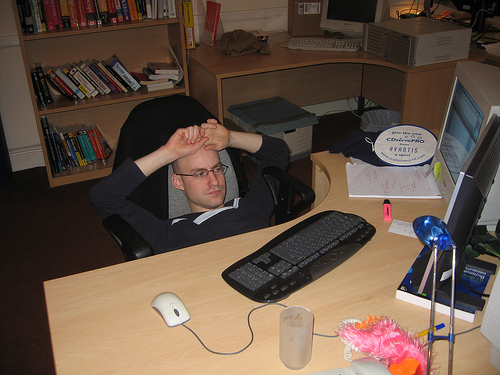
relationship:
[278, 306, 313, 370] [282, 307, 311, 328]
glass for drinking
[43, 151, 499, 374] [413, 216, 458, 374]
desk has a lamp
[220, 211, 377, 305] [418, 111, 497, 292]
keyboard to a computer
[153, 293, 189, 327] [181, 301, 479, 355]
mouse has a wire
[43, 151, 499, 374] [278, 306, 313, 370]
desk has a glass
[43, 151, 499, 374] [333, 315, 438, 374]
desk has a object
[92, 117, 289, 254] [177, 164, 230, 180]
man has on glasses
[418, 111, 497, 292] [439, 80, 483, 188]
computer has a screen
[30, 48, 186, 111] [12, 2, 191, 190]
books are on a book shelf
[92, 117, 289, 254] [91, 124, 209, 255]
man has a left arm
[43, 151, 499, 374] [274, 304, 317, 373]
desk has a glass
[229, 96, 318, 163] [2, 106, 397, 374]
file box on floor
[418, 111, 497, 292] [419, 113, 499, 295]
computer has a monitor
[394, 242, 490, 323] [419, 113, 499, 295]
book under monitor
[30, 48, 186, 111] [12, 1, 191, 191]
books are on bookshelf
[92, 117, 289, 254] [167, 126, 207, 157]
man has hands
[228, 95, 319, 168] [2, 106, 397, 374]
file box on floor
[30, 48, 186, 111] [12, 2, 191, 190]
books are in a book shelf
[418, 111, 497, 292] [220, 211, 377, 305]
computer has a keyboard